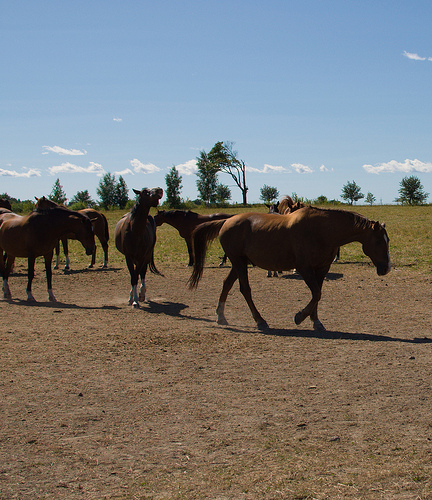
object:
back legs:
[219, 266, 237, 301]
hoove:
[310, 309, 318, 321]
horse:
[0, 193, 17, 274]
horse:
[153, 208, 240, 267]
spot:
[383, 234, 387, 244]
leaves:
[398, 173, 412, 193]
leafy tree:
[195, 149, 219, 206]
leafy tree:
[162, 166, 183, 209]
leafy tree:
[340, 180, 365, 204]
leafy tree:
[391, 174, 429, 205]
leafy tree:
[47, 177, 67, 205]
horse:
[277, 194, 340, 273]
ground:
[100, 367, 160, 410]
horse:
[115, 186, 168, 308]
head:
[132, 186, 163, 207]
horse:
[182, 205, 392, 330]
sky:
[1, 1, 432, 207]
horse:
[263, 201, 282, 277]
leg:
[229, 258, 264, 322]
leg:
[297, 258, 321, 321]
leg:
[310, 266, 330, 321]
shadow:
[205, 325, 432, 343]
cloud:
[0, 144, 432, 177]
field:
[10, 201, 432, 269]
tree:
[195, 139, 247, 204]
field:
[0, 263, 432, 465]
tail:
[185, 219, 224, 292]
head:
[362, 221, 391, 276]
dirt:
[0, 265, 432, 495]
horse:
[0, 207, 99, 301]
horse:
[34, 195, 110, 269]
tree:
[364, 191, 376, 205]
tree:
[212, 182, 233, 206]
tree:
[96, 172, 124, 211]